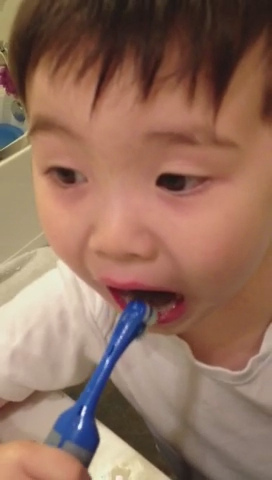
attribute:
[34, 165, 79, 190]
eye — brown 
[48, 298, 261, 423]
shirt — white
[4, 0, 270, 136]
short hair — black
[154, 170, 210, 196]
eye — black, white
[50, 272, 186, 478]
toothbrush — blue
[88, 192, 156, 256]
small nose — wide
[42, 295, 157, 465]
toothbrush — blue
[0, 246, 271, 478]
baby tee — white, crisp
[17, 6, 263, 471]
boy — brown 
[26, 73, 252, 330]
face — brown 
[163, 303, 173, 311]
teeth — clean, white, baby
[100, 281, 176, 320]
lips — tomato red, small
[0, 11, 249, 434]
baby — blue 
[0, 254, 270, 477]
shirt — white 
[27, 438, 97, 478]
finger — small, index